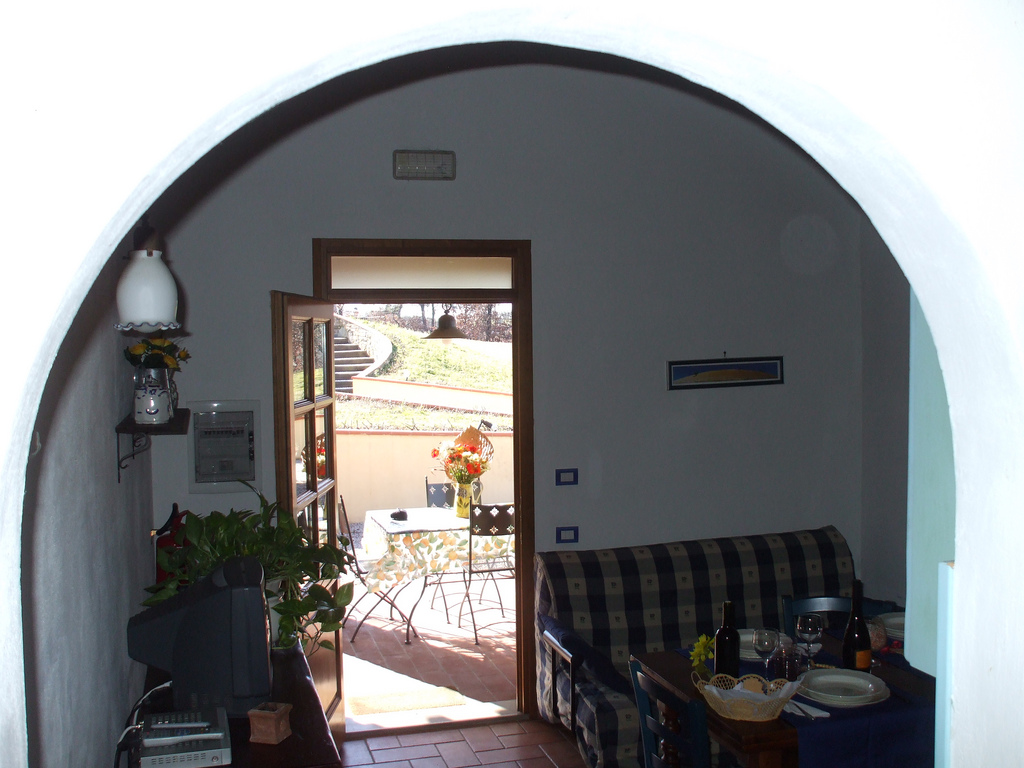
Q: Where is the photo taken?
A: Living room.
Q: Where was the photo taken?
A: At door to patio.